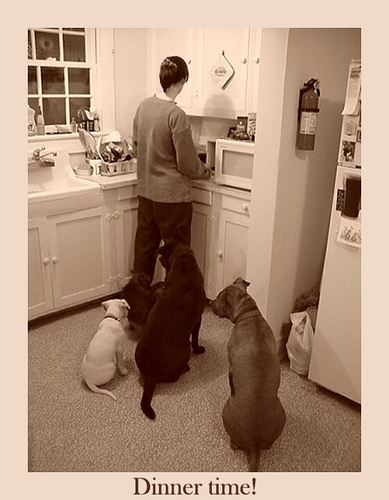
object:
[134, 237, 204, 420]
dog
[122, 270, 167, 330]
cat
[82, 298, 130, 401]
dog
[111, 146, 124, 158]
dishes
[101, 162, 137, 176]
drainer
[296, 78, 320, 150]
fire extinguisher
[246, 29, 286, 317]
wall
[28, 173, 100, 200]
sink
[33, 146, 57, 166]
faucet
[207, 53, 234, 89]
pot holder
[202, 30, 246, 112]
cabinet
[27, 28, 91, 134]
window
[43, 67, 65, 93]
panes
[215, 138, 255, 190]
microwave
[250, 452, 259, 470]
tail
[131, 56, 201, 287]
woman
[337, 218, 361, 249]
paper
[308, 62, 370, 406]
refrigerator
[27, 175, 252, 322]
counter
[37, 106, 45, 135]
dish soup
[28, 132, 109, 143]
window sill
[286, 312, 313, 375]
bag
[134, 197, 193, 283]
jeans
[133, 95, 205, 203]
shirt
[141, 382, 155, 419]
tail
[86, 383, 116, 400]
tail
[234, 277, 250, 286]
ear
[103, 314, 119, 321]
collar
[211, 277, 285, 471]
dog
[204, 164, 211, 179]
food